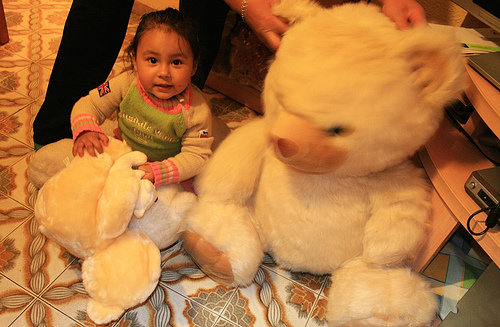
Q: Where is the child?
A: On the floor.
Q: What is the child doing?
A: Sitting.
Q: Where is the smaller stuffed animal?
A: In child's hands.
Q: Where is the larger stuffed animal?
A: Sitting next to child.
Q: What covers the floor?
A: Tiles.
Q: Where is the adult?
A: Behind the child.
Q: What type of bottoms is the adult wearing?
A: Black pants.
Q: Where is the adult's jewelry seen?
A: Right wrist.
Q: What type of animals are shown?
A: Bears.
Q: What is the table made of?
A: Wood.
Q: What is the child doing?
A: Sitting on the ground.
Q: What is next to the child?
A: A big stuffed animal.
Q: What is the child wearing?
A: A sweater.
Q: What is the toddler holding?
A: A teddy bear.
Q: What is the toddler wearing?
A: A sweater.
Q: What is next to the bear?
A: Shelves.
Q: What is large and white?
A: A stuffed bear.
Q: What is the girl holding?
A: A yellow teddy bear.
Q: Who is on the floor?
A: A child.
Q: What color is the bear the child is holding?
A: Tan.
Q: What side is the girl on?
A: Left side.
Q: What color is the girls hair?
A: Black.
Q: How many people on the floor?
A: One.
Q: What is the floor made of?
A: Tiles.